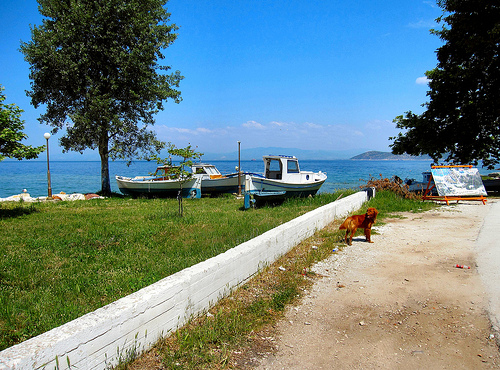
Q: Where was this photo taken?
A: Near the bay.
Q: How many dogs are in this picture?
A: One.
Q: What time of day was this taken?
A: During the day.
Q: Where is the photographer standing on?
A: On the dirt road.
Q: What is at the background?
A: The sea.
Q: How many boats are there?
A: Two.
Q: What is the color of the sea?
A: Blue.